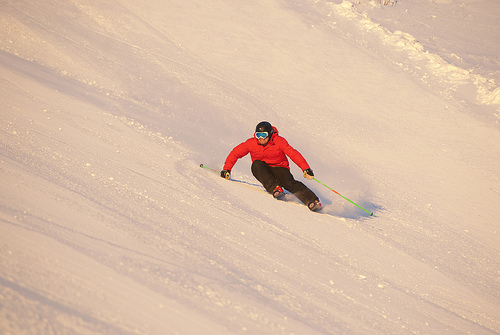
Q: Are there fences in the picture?
A: No, there are no fences.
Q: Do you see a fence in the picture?
A: No, there are no fences.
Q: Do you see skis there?
A: Yes, there are skis.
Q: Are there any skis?
A: Yes, there are skis.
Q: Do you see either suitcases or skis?
A: Yes, there are skis.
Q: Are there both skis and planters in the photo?
A: No, there are skis but no planters.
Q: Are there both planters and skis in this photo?
A: No, there are skis but no planters.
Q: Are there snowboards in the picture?
A: No, there are no snowboards.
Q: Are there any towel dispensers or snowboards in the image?
A: No, there are no snowboards or towel dispensers.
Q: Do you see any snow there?
A: Yes, there is snow.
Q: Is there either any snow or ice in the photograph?
A: Yes, there is snow.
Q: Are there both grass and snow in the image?
A: No, there is snow but no grass.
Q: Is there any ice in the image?
A: No, there is no ice.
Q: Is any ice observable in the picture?
A: No, there is no ice.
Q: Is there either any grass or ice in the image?
A: No, there are no ice or grass.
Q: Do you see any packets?
A: No, there are no packets.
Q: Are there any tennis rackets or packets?
A: No, there are no packets or tennis rackets.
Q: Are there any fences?
A: No, there are no fences.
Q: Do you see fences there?
A: No, there are no fences.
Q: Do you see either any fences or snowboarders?
A: No, there are no fences or snowboarders.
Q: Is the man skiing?
A: Yes, the man is skiing.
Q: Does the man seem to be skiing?
A: Yes, the man is skiing.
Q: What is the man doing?
A: The man is skiing.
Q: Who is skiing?
A: The man is skiing.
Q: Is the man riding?
A: No, the man is skiing.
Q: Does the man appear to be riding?
A: No, the man is skiing.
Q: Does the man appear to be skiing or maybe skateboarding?
A: The man is skiing.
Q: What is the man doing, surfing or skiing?
A: The man is skiing.